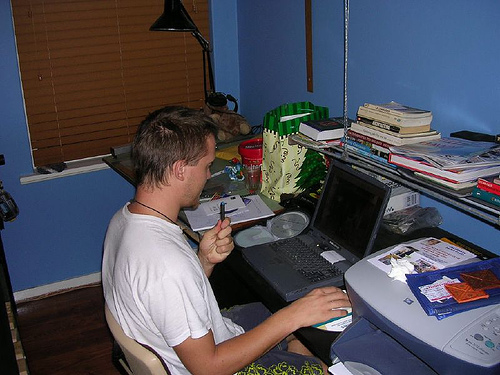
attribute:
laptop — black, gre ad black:
[241, 158, 391, 302]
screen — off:
[313, 164, 383, 257]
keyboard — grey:
[271, 234, 342, 288]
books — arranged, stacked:
[298, 96, 499, 207]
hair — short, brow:
[131, 105, 216, 193]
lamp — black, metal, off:
[148, 0, 217, 100]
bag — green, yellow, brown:
[259, 101, 329, 204]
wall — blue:
[237, 1, 499, 259]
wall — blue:
[1, 0, 241, 295]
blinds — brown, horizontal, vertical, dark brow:
[11, 1, 211, 169]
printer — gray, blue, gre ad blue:
[328, 234, 498, 373]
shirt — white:
[100, 198, 245, 374]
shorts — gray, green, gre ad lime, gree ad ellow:
[217, 302, 325, 374]